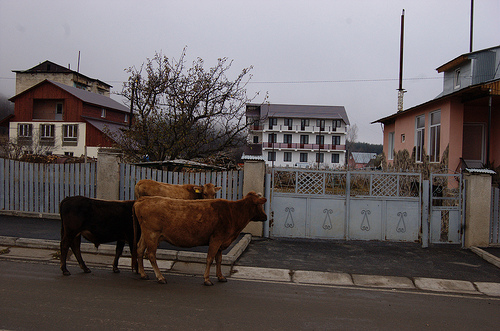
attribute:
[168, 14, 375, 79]
sky — gray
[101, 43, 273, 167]
branches — dark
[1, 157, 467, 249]
fence — white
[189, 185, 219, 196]
tag — yellow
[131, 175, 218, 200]
cow — brown, walking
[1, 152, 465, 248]
fencing — picket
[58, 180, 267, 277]
cow — black, smaller, darker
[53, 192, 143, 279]
cow — standing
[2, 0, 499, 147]
sky — light blue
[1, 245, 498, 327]
street — dark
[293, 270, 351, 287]
square — cement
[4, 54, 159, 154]
roof — slanted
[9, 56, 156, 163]
building — brown, yellow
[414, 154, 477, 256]
door — between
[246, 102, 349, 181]
building — white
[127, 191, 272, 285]
cow — brown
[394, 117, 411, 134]
pink — building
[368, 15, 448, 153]
poles — large, brown, sticking up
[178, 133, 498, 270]
gate — across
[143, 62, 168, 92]
leaves — small